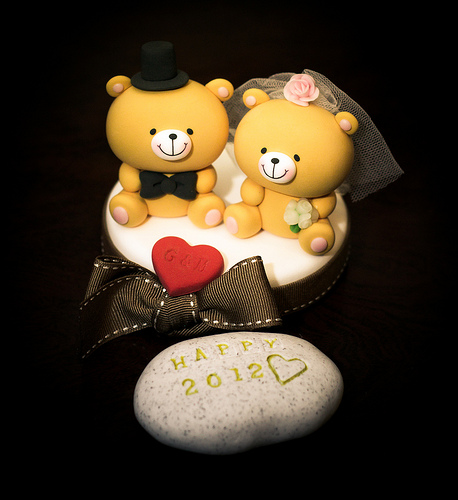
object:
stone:
[134, 328, 345, 456]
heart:
[266, 354, 308, 385]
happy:
[169, 338, 279, 369]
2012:
[181, 360, 266, 395]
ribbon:
[78, 255, 286, 359]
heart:
[153, 236, 227, 300]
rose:
[281, 73, 321, 108]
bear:
[224, 86, 360, 257]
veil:
[223, 68, 407, 202]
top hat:
[129, 41, 192, 94]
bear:
[100, 40, 233, 230]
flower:
[281, 198, 312, 233]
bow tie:
[137, 172, 202, 200]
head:
[104, 77, 235, 174]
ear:
[106, 74, 132, 98]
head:
[233, 89, 359, 199]